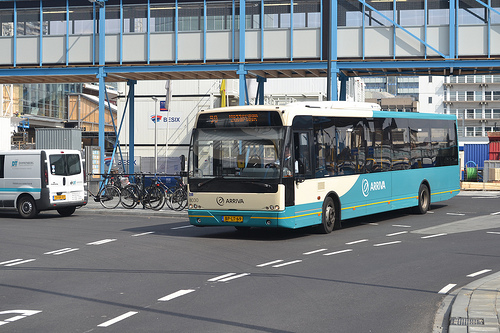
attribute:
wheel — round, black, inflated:
[318, 191, 344, 232]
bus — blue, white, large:
[182, 104, 468, 229]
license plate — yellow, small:
[215, 214, 248, 228]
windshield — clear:
[191, 123, 287, 185]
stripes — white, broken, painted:
[77, 228, 440, 328]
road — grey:
[9, 179, 498, 326]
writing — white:
[369, 176, 394, 195]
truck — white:
[1, 145, 92, 221]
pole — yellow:
[213, 78, 234, 109]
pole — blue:
[323, 68, 346, 106]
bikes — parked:
[89, 168, 197, 212]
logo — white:
[355, 178, 374, 206]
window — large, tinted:
[302, 121, 460, 167]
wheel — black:
[16, 195, 45, 219]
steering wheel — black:
[261, 157, 285, 177]